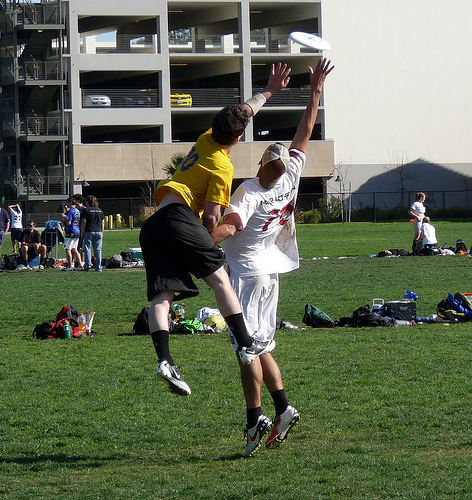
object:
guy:
[20, 221, 48, 270]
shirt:
[23, 229, 41, 244]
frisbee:
[286, 27, 331, 55]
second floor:
[169, 55, 243, 112]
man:
[210, 55, 335, 460]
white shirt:
[222, 148, 309, 280]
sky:
[338, 132, 375, 153]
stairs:
[0, 97, 39, 136]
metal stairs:
[33, 65, 67, 90]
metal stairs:
[33, 9, 69, 33]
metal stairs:
[53, 38, 90, 70]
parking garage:
[4, 0, 335, 230]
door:
[47, 144, 69, 194]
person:
[144, 260, 168, 338]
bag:
[300, 297, 337, 332]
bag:
[350, 306, 381, 326]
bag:
[380, 299, 416, 323]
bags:
[302, 301, 335, 327]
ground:
[24, 435, 64, 468]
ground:
[398, 426, 452, 489]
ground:
[340, 224, 388, 245]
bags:
[54, 318, 86, 340]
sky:
[343, 11, 374, 46]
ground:
[381, 95, 422, 122]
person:
[7, 271, 23, 324]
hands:
[60, 212, 66, 218]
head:
[27, 219, 36, 230]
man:
[138, 63, 293, 400]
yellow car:
[185, 139, 208, 155]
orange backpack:
[74, 321, 87, 338]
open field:
[306, 330, 471, 498]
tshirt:
[151, 125, 234, 217]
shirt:
[421, 223, 440, 246]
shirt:
[81, 207, 105, 232]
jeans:
[84, 232, 103, 268]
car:
[82, 88, 113, 108]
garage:
[0, 1, 335, 231]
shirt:
[152, 128, 235, 218]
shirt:
[223, 148, 307, 278]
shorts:
[228, 255, 280, 358]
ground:
[22, 344, 71, 387]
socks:
[245, 405, 266, 429]